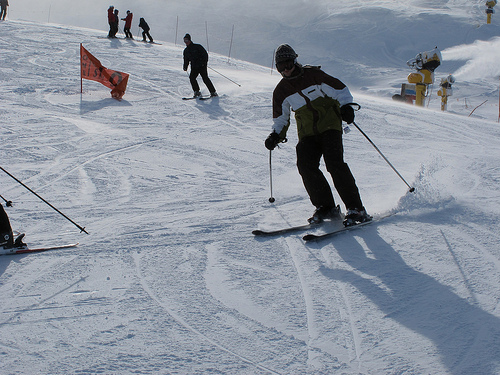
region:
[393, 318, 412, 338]
part of the snow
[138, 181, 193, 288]
edge of a hill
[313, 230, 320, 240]
part of a board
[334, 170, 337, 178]
part of a jacket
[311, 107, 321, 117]
part of a jacket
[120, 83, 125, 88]
part of a flag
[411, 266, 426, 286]
part of a shadow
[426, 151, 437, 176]
edge of a hill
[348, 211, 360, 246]
part of a skate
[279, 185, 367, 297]
This man is holding himself up on skis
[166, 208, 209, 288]
There is white snow that has been packed down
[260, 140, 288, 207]
This man is holding a ski pole in his hand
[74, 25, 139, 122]
There is a flag here that is on the hill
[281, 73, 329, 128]
This man is wearing a jacket with white stripes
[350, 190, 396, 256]
This man is wearing black snow boots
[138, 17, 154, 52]
This person is leaning on her skis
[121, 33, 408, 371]
Jackson Mingus is the one responsible for this photo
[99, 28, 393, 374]
This photo has a high degree of detail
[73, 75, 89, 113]
There is a pole that is in the snow here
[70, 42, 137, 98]
Orange flag with black letters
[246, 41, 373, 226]
Skier wearing a brown, white and green jacket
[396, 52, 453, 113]
Yellow and white machines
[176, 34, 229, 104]
Skier wearing an all black outfit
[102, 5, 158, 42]
A group of four skiers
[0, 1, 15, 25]
A lone skier in the distance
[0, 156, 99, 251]
The back of someone's skis and ski pole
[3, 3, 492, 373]
Beautiful snowy hills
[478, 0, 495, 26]
Lonely yellow and white machine in the distance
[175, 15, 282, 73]
Rods sticking out of snow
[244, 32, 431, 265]
man skiing in the snow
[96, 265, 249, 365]
white snow on the ground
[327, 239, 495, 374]
shadow in the snow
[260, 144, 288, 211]
ski pole in man's hand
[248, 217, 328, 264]
skiis used by a man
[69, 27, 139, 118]
flag in the snow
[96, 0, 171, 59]
people skiing on a hill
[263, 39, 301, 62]
hat on a skiier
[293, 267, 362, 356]
ski tracks in the snow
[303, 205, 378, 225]
ski boots on a man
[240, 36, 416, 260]
a man skiing on a slop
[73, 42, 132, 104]
a red flag in the snow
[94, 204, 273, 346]
tracks in the snow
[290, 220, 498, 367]
a shadow of a man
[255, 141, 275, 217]
a black ski pole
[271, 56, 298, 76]
black goggles on face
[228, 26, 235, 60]
a pole on the slop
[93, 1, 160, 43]
a group of skiers talking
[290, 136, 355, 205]
a black pair of pants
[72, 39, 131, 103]
a flag with writing on it